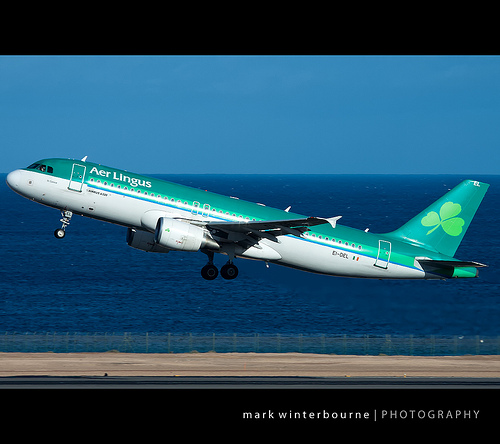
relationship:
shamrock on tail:
[414, 193, 467, 241] [392, 180, 493, 284]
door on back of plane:
[374, 236, 395, 270] [8, 156, 493, 286]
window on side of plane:
[109, 182, 117, 188] [8, 156, 493, 286]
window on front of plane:
[28, 162, 57, 174] [8, 156, 493, 286]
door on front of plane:
[66, 162, 87, 194] [8, 156, 493, 286]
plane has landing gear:
[8, 156, 493, 286] [197, 250, 243, 281]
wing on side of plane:
[215, 213, 342, 250] [8, 156, 493, 286]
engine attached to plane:
[152, 217, 226, 254] [8, 156, 493, 286]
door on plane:
[374, 236, 395, 270] [8, 156, 493, 286]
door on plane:
[66, 162, 87, 194] [8, 156, 493, 286]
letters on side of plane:
[87, 165, 156, 191] [8, 156, 493, 286]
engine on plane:
[124, 226, 175, 253] [8, 156, 493, 286]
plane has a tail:
[8, 156, 493, 286] [392, 180, 493, 284]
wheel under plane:
[222, 258, 239, 279] [8, 156, 493, 286]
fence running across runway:
[2, 333, 499, 356] [2, 349, 499, 387]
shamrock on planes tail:
[414, 193, 467, 241] [392, 180, 493, 284]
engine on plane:
[152, 217, 226, 254] [8, 156, 493, 286]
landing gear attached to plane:
[197, 250, 243, 281] [8, 156, 493, 286]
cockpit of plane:
[23, 158, 62, 182] [8, 156, 493, 286]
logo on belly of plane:
[350, 255, 362, 262] [8, 156, 493, 286]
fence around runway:
[2, 333, 499, 356] [2, 349, 499, 387]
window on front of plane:
[109, 182, 117, 188] [8, 156, 493, 286]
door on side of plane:
[374, 236, 395, 270] [8, 156, 493, 286]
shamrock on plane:
[414, 193, 467, 241] [8, 156, 493, 286]